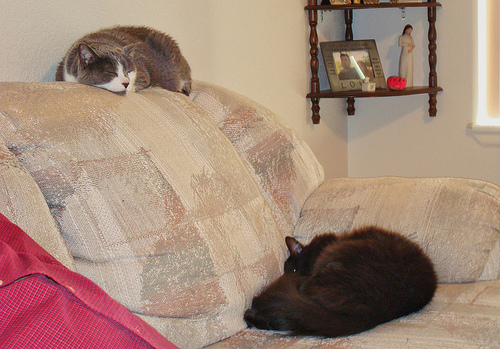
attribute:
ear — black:
[283, 233, 304, 258]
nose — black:
[121, 82, 128, 87]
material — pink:
[1, 212, 176, 347]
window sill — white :
[462, 114, 497, 149]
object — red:
[383, 75, 411, 87]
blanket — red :
[4, 215, 186, 346]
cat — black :
[241, 210, 439, 340]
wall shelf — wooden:
[307, 4, 445, 129]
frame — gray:
[316, 37, 390, 94]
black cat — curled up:
[243, 222, 438, 340]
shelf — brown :
[301, 2, 442, 123]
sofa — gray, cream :
[3, 72, 498, 347]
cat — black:
[231, 216, 432, 348]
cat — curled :
[243, 225, 439, 342]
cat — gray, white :
[58, 24, 193, 97]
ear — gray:
[122, 36, 143, 60]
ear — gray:
[77, 40, 98, 69]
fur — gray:
[121, 26, 171, 63]